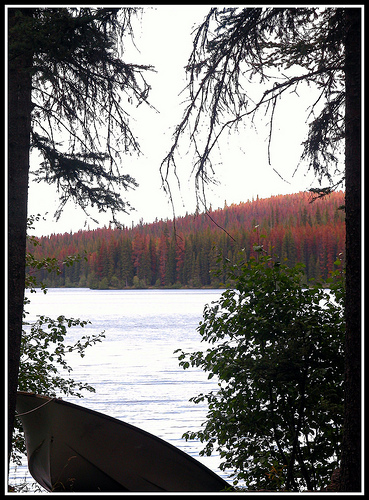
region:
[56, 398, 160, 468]
boat on the side of lake.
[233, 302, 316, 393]
The trees have green leaves.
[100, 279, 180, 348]
The water is blue.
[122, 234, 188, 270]
Bushes in the background.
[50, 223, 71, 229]
the sky is blue.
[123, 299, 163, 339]
The water is blue.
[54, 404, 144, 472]
Boat on the side of the lake.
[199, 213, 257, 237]
Red and green bushes.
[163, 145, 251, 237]
Hanging twigs from the trees.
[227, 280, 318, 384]
Green leaves on the trees.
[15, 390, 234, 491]
A boat pulled up on the shore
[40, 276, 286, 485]
A calm blue river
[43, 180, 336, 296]
A hill covered by trees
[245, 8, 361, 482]
A tall tree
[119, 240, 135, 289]
A conifer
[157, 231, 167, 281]
A tree with red leaves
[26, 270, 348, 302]
The shoreline of a river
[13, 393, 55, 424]
A rope attached to a boat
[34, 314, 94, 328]
Green leaves on a branch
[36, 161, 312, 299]
A forest under an overcast sky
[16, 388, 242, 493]
part of a boat sticking up on the shore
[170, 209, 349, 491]
the tree on the side of the boat is green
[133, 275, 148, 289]
green trees on the opposite shore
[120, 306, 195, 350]
an area of water that is choppy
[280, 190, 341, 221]
the trees on the top of the hill are changing color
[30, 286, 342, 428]
the body of water is a river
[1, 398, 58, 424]
the rope is attached to the boat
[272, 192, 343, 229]
the trees leaves have turned red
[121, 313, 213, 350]
the riply water is blue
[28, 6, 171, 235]
the tree is an evergreen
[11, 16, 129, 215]
tree with green leaves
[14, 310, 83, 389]
tree with green leaves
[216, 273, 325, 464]
tree with green leaves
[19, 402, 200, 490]
boat near river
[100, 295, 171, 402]
blue and white water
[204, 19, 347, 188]
tree with green leaves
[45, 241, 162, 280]
trees with red and green leaves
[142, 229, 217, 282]
trees with red and green leaves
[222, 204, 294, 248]
trees with red and green leaves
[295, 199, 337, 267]
trees with red and green leaves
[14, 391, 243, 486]
boat on the lake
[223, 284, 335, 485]
tree on the lake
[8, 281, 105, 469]
tree on the lake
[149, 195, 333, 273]
colorful forest on the lake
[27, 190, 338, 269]
trees with green leaves on the lake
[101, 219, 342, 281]
trees with red leaves on the lake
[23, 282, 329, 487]
the water is clear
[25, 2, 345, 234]
the sky is gray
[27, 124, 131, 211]
the branches are dangling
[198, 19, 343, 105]
branches dangling over the lake